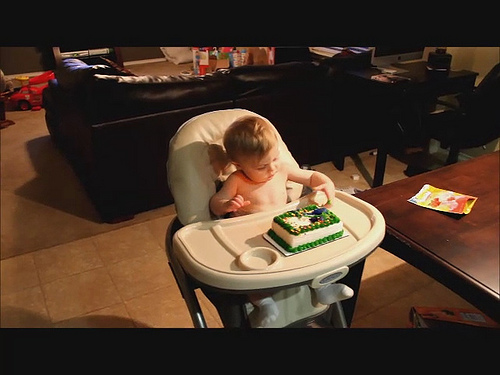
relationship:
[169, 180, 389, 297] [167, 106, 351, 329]
tray on chair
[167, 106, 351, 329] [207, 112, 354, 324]
chair for baby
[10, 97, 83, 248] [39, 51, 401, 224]
rug in area with couch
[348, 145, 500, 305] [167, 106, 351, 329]
table to right of chair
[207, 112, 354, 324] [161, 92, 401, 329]
baby in a highchair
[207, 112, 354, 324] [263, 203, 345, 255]
baby eating cake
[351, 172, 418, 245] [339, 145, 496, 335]
corner of a table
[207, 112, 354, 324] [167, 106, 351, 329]
baby sitting in a chair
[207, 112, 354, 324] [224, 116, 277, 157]
baby with blonde hair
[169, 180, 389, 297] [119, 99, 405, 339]
tray on a highchair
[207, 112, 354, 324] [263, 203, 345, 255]
baby ready to eat a cake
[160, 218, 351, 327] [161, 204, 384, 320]
frame of chair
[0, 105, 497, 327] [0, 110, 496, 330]
floor covered in tile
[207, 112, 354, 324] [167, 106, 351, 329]
baby in chair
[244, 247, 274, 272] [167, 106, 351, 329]
cupholder on chair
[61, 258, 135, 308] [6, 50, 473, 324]
floor in kitchen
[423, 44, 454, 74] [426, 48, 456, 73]
base of lamp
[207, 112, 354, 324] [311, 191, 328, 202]
baby holding object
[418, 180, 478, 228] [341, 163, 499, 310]
paper on table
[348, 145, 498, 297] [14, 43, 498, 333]
table in photo